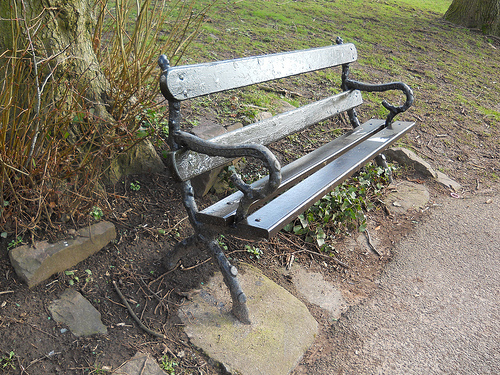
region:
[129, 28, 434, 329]
a metal and wood bench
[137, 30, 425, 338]
a place for people to sit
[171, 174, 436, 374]
stone slabs under bench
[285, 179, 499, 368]
a part of the gray road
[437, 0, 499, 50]
a tree trunk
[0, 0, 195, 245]
a tree with a bush next to the bench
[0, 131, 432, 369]
a dirt patch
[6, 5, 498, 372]
a scene outside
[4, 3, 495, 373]
a scene during the day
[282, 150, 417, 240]
a shrub under the bench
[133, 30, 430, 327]
The bench is sitting on the ground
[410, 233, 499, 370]
The street is asphalt and gray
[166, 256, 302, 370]
A block of gray cement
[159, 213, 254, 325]
The leg of the bench is steel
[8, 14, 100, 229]
The branches on the tree are brown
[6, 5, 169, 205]
The tree trunk is gray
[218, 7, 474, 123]
The land has some green grass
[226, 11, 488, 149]
The land has some dead grass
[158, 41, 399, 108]
The top part of the bench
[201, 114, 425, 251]
The seat of the bench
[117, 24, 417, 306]
Bench sitting on the side of road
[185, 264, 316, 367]
Rocks on side of pavement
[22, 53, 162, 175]
Grass growing on side of road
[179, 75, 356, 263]
The bench is metal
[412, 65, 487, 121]
Ground is patchy grass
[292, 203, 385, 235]
Leaves growing under the bench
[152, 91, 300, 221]
Arm rest on the bench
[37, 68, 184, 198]
Tree trunk behind the bench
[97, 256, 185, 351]
Sticks on the ground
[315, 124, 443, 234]
Shadow on the bench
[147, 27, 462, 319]
bench beside the sidewalk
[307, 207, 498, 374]
pathway in front of bench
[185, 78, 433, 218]
armrests of park bench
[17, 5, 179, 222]
tree next to park bench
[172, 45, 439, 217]
four planks of park bench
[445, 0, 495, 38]
tree trunk on the right side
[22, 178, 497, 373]
cement pavers around park bench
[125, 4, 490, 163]
patchy grass around park bench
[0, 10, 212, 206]
tall grass around tree trunk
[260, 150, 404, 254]
weeds underneath park bench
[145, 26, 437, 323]
bench on stone slabs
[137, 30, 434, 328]
bench with minimal slats on back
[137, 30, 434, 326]
bench with minimal slats on bottom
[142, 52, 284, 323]
metal end and arm rest of bench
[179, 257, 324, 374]
a nearly square slab of stone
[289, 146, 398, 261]
leaves under the bench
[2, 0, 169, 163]
trunk of a tree behind the bench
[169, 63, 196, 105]
rivets for attaching the slats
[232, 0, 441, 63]
scattered patches of grass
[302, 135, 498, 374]
paved walkway in front of bench